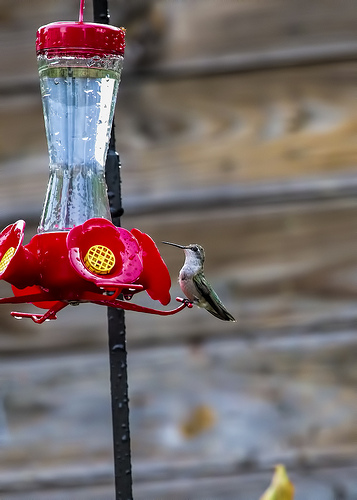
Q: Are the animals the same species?
A: Yes, all the animals are birds.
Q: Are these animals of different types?
A: No, all the animals are birds.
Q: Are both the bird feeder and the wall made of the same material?
A: No, the feeder is made of glass and the wall is made of wood.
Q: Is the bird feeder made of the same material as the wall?
A: No, the feeder is made of glass and the wall is made of wood.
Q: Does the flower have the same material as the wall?
A: No, the flower is made of plastic and the wall is made of wood.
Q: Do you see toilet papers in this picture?
A: No, there are no toilet papers.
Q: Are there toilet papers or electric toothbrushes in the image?
A: No, there are no toilet papers or electric toothbrushes.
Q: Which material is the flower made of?
A: The flower is made of plastic.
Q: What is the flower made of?
A: The flower is made of plastic.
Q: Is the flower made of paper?
A: No, the flower is made of plastic.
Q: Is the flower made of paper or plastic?
A: The flower is made of plastic.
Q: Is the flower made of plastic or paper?
A: The flower is made of plastic.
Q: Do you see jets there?
A: No, there are no jets.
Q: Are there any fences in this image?
A: No, there are no fences.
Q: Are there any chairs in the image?
A: No, there are no chairs.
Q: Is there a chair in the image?
A: No, there are no chairs.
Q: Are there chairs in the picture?
A: No, there are no chairs.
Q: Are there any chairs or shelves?
A: No, there are no chairs or shelves.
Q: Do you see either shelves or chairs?
A: No, there are no chairs or shelves.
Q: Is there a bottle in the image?
A: No, there are no bottles.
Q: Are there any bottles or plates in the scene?
A: No, there are no bottles or plates.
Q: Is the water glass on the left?
A: Yes, the water glass is on the left of the image.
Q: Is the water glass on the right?
A: No, the water glass is on the left of the image.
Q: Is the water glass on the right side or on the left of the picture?
A: The water glass is on the left of the image.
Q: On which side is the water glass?
A: The water glass is on the left of the image.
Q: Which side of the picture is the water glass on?
A: The water glass is on the left of the image.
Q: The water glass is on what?
A: The water glass is on the feeder.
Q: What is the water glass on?
A: The water glass is on the feeder.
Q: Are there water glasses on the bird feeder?
A: Yes, there is a water glass on the feeder.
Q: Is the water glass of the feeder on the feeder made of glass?
A: Yes, the water glass is on the feeder.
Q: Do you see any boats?
A: No, there are no boats.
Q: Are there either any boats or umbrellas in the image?
A: No, there are no boats or umbrellas.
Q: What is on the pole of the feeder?
A: The water is on the pole.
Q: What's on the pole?
A: The water is on the pole.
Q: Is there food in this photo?
A: Yes, there is food.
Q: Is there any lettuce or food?
A: Yes, there is food.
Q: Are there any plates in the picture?
A: No, there are no plates.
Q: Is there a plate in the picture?
A: No, there are no plates.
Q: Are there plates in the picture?
A: No, there are no plates.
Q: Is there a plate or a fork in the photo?
A: No, there are no plates or forks.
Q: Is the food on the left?
A: Yes, the food is on the left of the image.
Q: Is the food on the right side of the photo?
A: No, the food is on the left of the image.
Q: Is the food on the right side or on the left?
A: The food is on the left of the image.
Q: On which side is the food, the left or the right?
A: The food is on the left of the image.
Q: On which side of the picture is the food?
A: The food is on the left of the image.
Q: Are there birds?
A: Yes, there is a bird.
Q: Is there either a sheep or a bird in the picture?
A: Yes, there is a bird.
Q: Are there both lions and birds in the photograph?
A: No, there is a bird but no lions.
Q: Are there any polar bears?
A: No, there are no polar bears.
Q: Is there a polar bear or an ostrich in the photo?
A: No, there are no polar bears or ostriches.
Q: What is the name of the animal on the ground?
A: The animal is a bird.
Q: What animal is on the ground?
A: The animal is a bird.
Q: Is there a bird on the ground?
A: Yes, there is a bird on the ground.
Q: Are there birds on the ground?
A: Yes, there is a bird on the ground.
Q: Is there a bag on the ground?
A: No, there is a bird on the ground.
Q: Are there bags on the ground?
A: No, there is a bird on the ground.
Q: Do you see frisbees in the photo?
A: No, there are no frisbees.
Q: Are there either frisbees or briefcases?
A: No, there are no frisbees or briefcases.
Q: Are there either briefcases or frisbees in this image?
A: No, there are no frisbees or briefcases.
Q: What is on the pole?
A: The water is on the pole.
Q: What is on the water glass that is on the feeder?
A: The water is on the water glass.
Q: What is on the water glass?
A: The water is on the water glass.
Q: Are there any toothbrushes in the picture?
A: No, there are no toothbrushes.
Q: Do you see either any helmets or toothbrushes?
A: No, there are no toothbrushes or helmets.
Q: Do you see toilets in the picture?
A: No, there are no toilets.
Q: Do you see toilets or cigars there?
A: No, there are no toilets or cigars.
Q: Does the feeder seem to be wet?
A: Yes, the feeder is wet.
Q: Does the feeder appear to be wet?
A: Yes, the feeder is wet.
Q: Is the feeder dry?
A: No, the feeder is wet.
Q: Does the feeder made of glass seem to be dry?
A: No, the feeder is wet.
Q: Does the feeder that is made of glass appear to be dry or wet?
A: The feeder is wet.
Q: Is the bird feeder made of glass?
A: Yes, the feeder is made of glass.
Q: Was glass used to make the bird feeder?
A: Yes, the feeder is made of glass.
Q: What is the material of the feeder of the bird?
A: The feeder is made of glass.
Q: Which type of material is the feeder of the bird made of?
A: The feeder is made of glass.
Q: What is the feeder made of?
A: The feeder is made of glass.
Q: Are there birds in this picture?
A: Yes, there is a bird.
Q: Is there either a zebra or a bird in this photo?
A: Yes, there is a bird.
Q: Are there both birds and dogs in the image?
A: No, there is a bird but no dogs.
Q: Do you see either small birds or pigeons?
A: Yes, there is a small bird.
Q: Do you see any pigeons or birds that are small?
A: Yes, the bird is small.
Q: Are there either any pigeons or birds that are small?
A: Yes, the bird is small.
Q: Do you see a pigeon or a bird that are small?
A: Yes, the bird is small.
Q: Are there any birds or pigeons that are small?
A: Yes, the bird is small.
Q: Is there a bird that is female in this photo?
A: Yes, there is a female bird.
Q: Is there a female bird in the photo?
A: Yes, there is a female bird.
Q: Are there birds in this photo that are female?
A: Yes, there is a bird that is female.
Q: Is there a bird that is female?
A: Yes, there is a bird that is female.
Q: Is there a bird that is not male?
A: Yes, there is a female bird.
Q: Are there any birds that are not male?
A: Yes, there is a female bird.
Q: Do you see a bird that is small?
A: Yes, there is a small bird.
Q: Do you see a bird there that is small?
A: Yes, there is a bird that is small.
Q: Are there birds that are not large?
A: Yes, there is a small bird.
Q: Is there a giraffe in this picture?
A: No, there are no giraffes.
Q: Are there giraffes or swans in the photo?
A: No, there are no giraffes or swans.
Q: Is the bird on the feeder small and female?
A: Yes, the bird is small and female.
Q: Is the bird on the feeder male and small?
A: No, the bird is small but female.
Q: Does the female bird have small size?
A: Yes, the bird is small.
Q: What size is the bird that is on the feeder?
A: The bird is small.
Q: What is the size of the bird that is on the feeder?
A: The bird is small.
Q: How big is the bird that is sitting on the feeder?
A: The bird is small.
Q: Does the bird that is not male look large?
A: No, the bird is small.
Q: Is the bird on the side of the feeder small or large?
A: The bird is small.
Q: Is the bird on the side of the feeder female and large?
A: No, the bird is female but small.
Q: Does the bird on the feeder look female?
A: Yes, the bird is female.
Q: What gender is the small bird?
A: The bird is female.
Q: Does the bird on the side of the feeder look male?
A: No, the bird is female.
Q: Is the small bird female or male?
A: The bird is female.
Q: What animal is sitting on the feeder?
A: The bird is sitting on the feeder.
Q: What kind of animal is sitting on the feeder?
A: The animal is a bird.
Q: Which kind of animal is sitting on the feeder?
A: The animal is a bird.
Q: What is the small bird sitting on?
A: The bird is sitting on the feeder.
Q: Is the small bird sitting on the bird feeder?
A: Yes, the bird is sitting on the feeder.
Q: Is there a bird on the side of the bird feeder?
A: Yes, there is a bird on the side of the feeder.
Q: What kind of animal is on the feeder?
A: The animal is a bird.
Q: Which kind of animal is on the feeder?
A: The animal is a bird.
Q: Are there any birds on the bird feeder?
A: Yes, there is a bird on the feeder.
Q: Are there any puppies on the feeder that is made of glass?
A: No, there is a bird on the feeder.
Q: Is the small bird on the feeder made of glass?
A: Yes, the bird is on the feeder.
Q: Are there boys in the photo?
A: No, there are no boys.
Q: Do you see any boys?
A: No, there are no boys.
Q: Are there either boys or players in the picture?
A: No, there are no boys or players.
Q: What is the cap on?
A: The cap is on the feeder.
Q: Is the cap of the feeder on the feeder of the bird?
A: Yes, the cap is on the feeder.